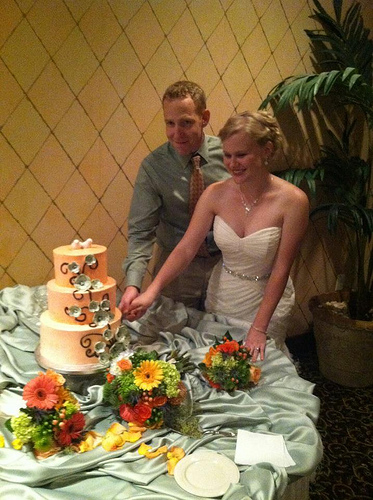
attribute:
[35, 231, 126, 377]
cake — wedding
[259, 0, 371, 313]
plant — large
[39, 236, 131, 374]
cake — beautiful, three-tier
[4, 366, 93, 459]
flower bouquet — fresh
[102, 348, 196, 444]
flower bouquet — fresh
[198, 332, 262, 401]
flower bouquet — fresh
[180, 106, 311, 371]
dress — white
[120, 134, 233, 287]
shirt — green, gray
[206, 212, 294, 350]
dress — white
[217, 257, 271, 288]
belt — silver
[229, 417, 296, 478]
napkin — white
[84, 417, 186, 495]
petals — yellow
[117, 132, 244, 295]
shirt — button down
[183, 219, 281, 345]
dress — wedding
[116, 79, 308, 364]
couple — happy